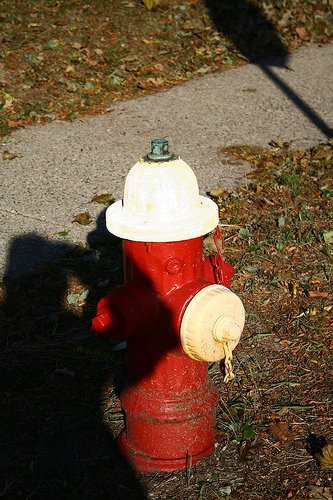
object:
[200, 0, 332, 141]
shadow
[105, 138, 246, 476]
hydrant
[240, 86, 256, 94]
debris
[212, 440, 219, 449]
stone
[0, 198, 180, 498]
shadow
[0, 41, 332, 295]
sidewalk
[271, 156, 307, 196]
grass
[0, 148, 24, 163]
leaves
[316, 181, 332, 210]
grass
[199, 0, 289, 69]
black shadow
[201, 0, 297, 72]
sign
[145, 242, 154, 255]
bolt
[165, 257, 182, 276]
screw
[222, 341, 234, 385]
chain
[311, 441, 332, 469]
leaf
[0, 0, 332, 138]
grass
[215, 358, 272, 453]
grass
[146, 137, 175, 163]
bolt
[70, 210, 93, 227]
leaf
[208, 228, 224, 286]
chain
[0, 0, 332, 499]
patch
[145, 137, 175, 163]
top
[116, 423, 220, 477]
bottom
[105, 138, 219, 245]
cap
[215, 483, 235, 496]
rock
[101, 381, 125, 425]
grass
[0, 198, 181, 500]
person